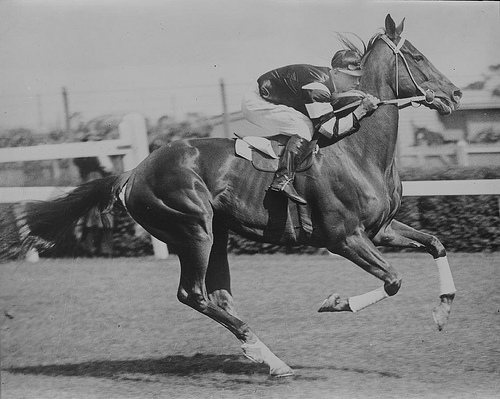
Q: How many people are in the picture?
A: 1.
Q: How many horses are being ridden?
A: 1.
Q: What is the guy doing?
A: Riding a horse.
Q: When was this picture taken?
A: Day time.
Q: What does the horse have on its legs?
A: Polo wraps.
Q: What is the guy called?
A: A jockey.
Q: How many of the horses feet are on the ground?
A: 0.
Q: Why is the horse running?
A: Its racing.